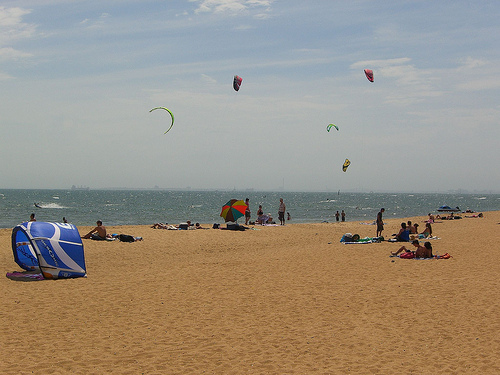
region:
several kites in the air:
[149, 66, 401, 172]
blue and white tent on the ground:
[10, 220, 88, 280]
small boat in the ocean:
[437, 202, 460, 214]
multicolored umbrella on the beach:
[218, 198, 248, 225]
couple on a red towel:
[393, 240, 450, 261]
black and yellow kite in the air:
[340, 159, 352, 174]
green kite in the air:
[148, 103, 175, 138]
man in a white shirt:
[275, 196, 287, 223]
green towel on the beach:
[339, 232, 374, 245]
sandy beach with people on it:
[1, 210, 499, 374]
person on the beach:
[268, 196, 285, 228]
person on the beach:
[86, 219, 109, 242]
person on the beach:
[398, 241, 426, 258]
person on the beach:
[416, 220, 436, 240]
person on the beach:
[340, 209, 350, 224]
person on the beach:
[373, 203, 385, 236]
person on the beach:
[342, 231, 365, 245]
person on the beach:
[181, 220, 193, 229]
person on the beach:
[239, 190, 258, 223]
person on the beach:
[256, 205, 266, 228]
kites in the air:
[146, 67, 378, 171]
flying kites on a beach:
[3, 61, 498, 374]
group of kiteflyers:
[85, 67, 453, 270]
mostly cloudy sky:
[1, 0, 499, 190]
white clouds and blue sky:
[1, 0, 499, 192]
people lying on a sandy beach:
[150, 220, 209, 232]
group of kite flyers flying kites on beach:
[29, 67, 375, 227]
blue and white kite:
[5, 221, 82, 274]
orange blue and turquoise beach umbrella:
[220, 198, 247, 223]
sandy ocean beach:
[0, 190, 473, 374]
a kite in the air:
[226, 70, 247, 97]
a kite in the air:
[357, 67, 375, 84]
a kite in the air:
[147, 103, 177, 136]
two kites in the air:
[322, 120, 355, 175]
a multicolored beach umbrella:
[215, 197, 248, 225]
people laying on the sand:
[389, 237, 452, 263]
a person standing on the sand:
[373, 203, 386, 236]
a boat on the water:
[436, 203, 463, 212]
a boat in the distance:
[66, 178, 91, 191]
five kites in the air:
[144, 59, 375, 173]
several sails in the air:
[147, 68, 377, 174]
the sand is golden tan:
[2, 205, 498, 373]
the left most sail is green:
[148, 105, 175, 134]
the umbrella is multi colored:
[220, 200, 249, 229]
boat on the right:
[431, 202, 460, 215]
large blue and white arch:
[11, 219, 88, 279]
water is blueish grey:
[1, 187, 496, 229]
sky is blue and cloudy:
[0, 1, 498, 194]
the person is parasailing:
[31, 198, 42, 212]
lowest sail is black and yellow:
[338, 156, 353, 171]